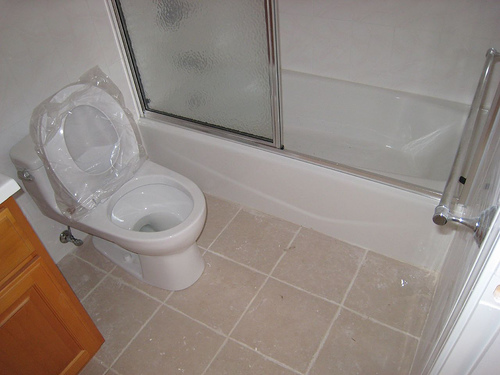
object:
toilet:
[9, 66, 210, 293]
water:
[132, 214, 172, 237]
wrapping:
[30, 65, 150, 223]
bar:
[432, 48, 497, 250]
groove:
[267, 274, 341, 308]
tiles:
[229, 226, 367, 374]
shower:
[106, 2, 497, 229]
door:
[109, 2, 284, 151]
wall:
[416, 120, 499, 374]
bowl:
[81, 160, 205, 295]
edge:
[84, 161, 203, 243]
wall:
[1, 1, 139, 78]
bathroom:
[1, 3, 500, 374]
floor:
[223, 271, 434, 373]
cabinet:
[1, 198, 105, 374]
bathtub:
[137, 73, 487, 280]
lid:
[42, 85, 142, 208]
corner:
[1, 176, 22, 214]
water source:
[12, 134, 71, 225]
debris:
[399, 276, 407, 288]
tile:
[275, 0, 500, 112]